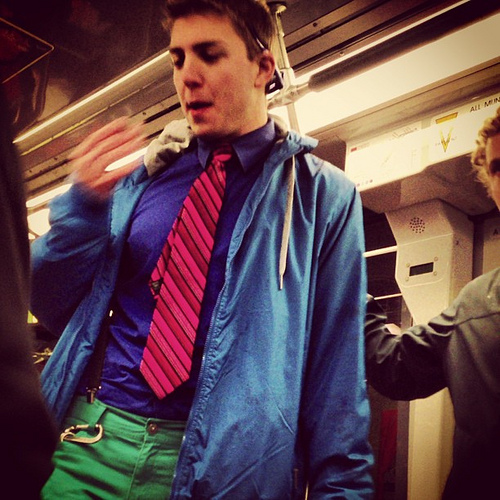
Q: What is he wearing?
A: Tie.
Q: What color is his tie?
A: Red.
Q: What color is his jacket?
A: Blue.